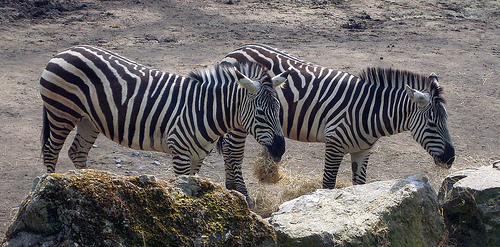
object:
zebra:
[37, 44, 286, 177]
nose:
[269, 135, 288, 159]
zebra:
[217, 44, 455, 189]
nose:
[440, 146, 455, 169]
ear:
[235, 71, 258, 92]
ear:
[273, 66, 297, 89]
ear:
[402, 83, 429, 107]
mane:
[187, 61, 269, 81]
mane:
[360, 68, 435, 90]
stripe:
[67, 55, 89, 68]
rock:
[7, 168, 278, 246]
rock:
[266, 174, 450, 246]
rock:
[437, 168, 499, 241]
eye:
[256, 108, 266, 116]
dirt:
[0, 0, 145, 42]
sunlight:
[282, 201, 302, 213]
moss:
[17, 168, 294, 246]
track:
[112, 31, 180, 47]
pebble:
[377, 56, 383, 61]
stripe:
[337, 75, 347, 104]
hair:
[39, 109, 46, 146]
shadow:
[389, 173, 421, 194]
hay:
[254, 150, 285, 182]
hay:
[426, 162, 451, 187]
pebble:
[23, 173, 28, 177]